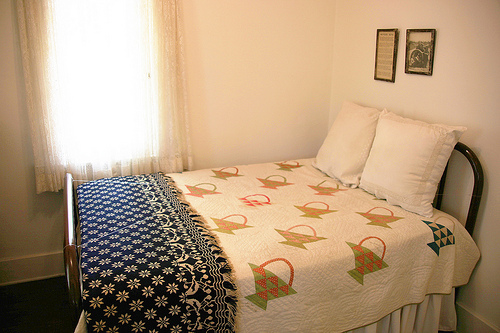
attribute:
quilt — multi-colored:
[163, 165, 463, 309]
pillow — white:
[366, 111, 448, 205]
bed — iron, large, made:
[57, 71, 478, 325]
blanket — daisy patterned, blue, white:
[65, 167, 227, 326]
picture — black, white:
[401, 26, 432, 76]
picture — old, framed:
[368, 25, 399, 88]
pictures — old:
[358, 26, 446, 83]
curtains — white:
[15, 2, 197, 189]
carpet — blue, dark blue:
[0, 267, 77, 329]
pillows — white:
[308, 97, 458, 219]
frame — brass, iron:
[340, 106, 489, 234]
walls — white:
[4, 3, 487, 298]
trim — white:
[2, 250, 73, 285]